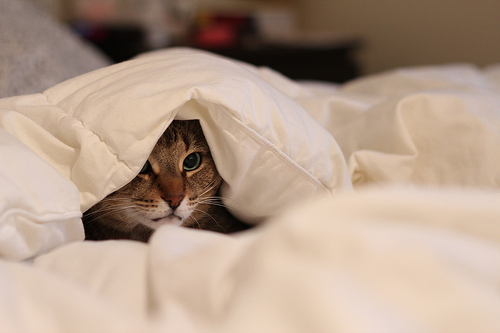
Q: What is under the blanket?
A: The cat.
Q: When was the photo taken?
A: Day time.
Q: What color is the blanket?
A: White.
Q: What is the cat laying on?
A: The bed.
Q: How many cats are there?
A: One.